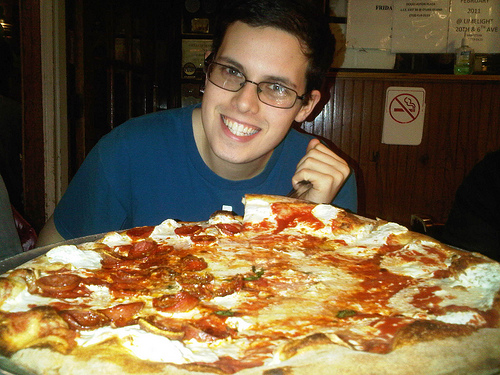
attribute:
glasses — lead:
[199, 48, 311, 115]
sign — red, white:
[380, 78, 426, 153]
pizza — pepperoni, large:
[0, 169, 499, 370]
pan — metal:
[2, 210, 499, 372]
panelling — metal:
[211, 61, 496, 233]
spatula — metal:
[242, 158, 347, 212]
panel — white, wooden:
[41, 3, 71, 246]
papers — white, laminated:
[332, 6, 496, 70]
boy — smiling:
[24, 0, 390, 240]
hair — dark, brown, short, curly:
[198, 0, 348, 89]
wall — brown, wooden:
[270, 70, 499, 243]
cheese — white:
[198, 225, 366, 336]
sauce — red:
[352, 248, 403, 322]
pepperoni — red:
[100, 245, 165, 289]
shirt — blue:
[43, 97, 375, 249]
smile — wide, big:
[213, 104, 267, 146]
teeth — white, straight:
[218, 113, 273, 148]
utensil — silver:
[290, 157, 318, 203]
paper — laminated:
[342, 0, 397, 56]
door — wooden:
[50, 0, 182, 238]